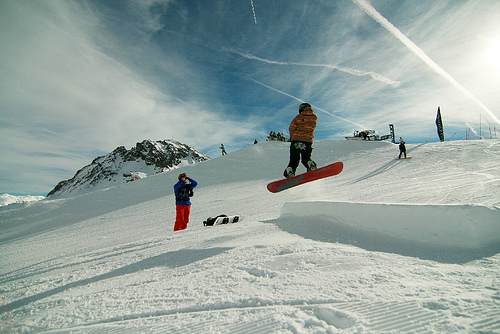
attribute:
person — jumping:
[281, 94, 322, 177]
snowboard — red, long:
[265, 162, 351, 192]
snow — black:
[344, 260, 367, 276]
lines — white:
[231, 44, 293, 104]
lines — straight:
[318, 290, 358, 316]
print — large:
[305, 295, 337, 332]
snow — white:
[235, 235, 292, 298]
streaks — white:
[263, 27, 284, 118]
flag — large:
[430, 100, 449, 150]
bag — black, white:
[197, 200, 241, 230]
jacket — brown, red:
[288, 105, 328, 145]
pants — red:
[164, 199, 205, 230]